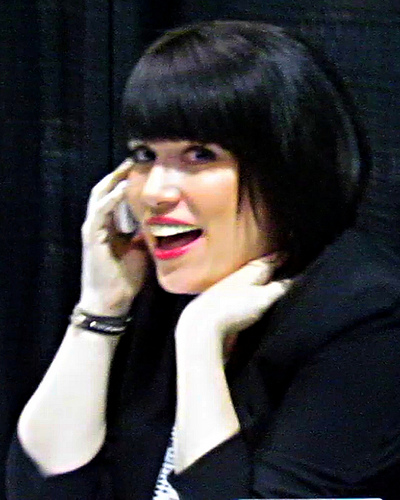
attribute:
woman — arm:
[5, 20, 398, 498]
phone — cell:
[107, 176, 143, 234]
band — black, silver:
[67, 308, 131, 338]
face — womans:
[118, 133, 256, 296]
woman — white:
[42, 58, 285, 466]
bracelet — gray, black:
[47, 298, 153, 344]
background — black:
[4, 0, 399, 404]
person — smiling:
[83, 28, 398, 397]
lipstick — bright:
[129, 206, 186, 234]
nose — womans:
[142, 158, 174, 208]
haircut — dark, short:
[122, 24, 374, 288]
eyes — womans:
[128, 141, 229, 170]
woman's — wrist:
[5, 16, 396, 497]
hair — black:
[119, 16, 375, 288]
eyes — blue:
[127, 140, 225, 172]